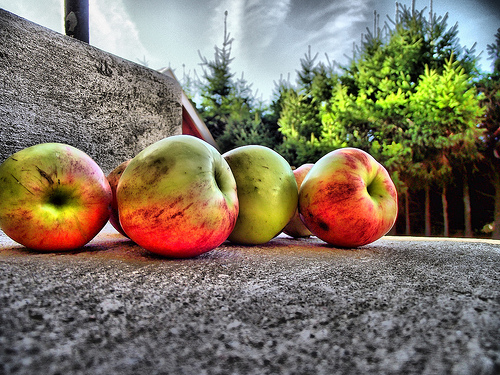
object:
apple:
[221, 145, 298, 246]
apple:
[299, 147, 398, 250]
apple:
[116, 134, 240, 260]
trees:
[409, 1, 443, 238]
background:
[3, 0, 498, 238]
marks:
[116, 156, 179, 206]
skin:
[222, 143, 298, 247]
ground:
[0, 237, 498, 372]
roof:
[162, 65, 224, 153]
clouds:
[241, 1, 345, 42]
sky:
[1, 2, 496, 113]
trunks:
[404, 175, 500, 238]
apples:
[0, 133, 399, 258]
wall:
[1, 6, 178, 134]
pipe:
[65, 0, 89, 46]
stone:
[3, 233, 499, 373]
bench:
[3, 6, 500, 374]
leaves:
[371, 80, 418, 117]